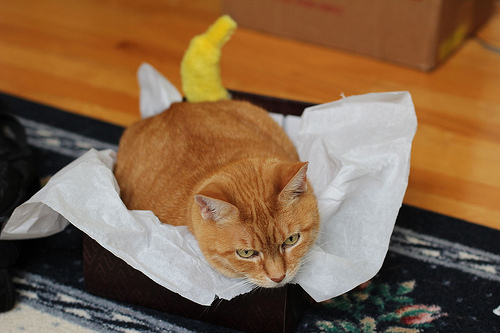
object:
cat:
[110, 99, 332, 292]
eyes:
[279, 229, 304, 252]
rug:
[382, 229, 499, 331]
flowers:
[390, 303, 451, 326]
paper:
[317, 89, 419, 207]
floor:
[0, 0, 136, 124]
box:
[227, 0, 498, 75]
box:
[80, 229, 313, 332]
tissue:
[2, 148, 115, 256]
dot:
[243, 249, 250, 255]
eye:
[233, 246, 261, 261]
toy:
[178, 12, 240, 101]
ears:
[275, 159, 310, 210]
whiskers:
[294, 242, 336, 281]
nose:
[267, 273, 287, 283]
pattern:
[310, 284, 445, 331]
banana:
[178, 12, 240, 105]